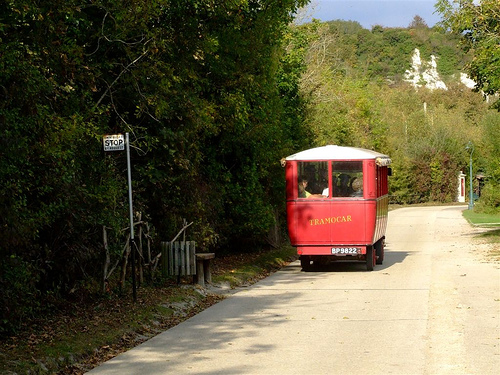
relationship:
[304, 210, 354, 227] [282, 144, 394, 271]
gold letters on bus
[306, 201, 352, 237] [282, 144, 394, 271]
gold letters on bus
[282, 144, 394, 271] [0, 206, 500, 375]
bus on ground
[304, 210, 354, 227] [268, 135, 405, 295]
gold letters on car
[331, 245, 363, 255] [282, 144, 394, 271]
license plate on bus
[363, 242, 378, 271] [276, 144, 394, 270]
wheel on car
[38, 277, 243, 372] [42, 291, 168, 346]
grass on ground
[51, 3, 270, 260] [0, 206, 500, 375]
tree on side of ground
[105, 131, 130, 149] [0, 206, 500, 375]
sign on side of ground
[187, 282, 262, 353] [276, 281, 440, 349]
shadows are on side of road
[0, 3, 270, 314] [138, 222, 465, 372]
tree are along side of road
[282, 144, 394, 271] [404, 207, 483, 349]
bus on road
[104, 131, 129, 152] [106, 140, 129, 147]
sign has on it stop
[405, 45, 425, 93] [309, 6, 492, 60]
structure in background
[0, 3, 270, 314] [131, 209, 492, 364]
tree along side of road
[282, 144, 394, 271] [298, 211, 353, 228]
bus with letters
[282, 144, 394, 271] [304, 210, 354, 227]
bus with gold letters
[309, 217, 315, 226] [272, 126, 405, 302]
letter painted on red train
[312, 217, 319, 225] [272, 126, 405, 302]
letter painted on red train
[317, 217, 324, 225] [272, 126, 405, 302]
letter painted on red train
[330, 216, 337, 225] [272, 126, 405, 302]
letter painted on red train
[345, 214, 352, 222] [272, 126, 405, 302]
letter painted on red train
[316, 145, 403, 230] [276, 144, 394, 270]
window built into car